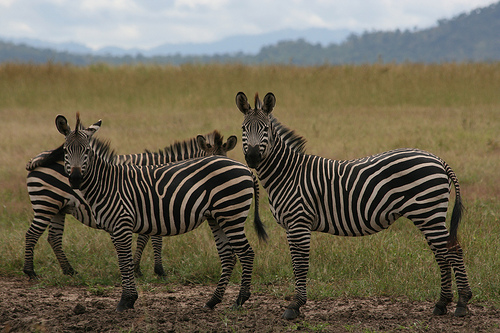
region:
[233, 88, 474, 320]
zebra is next to zebra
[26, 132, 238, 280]
zebra is next to zebra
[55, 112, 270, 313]
zebra is next to zebra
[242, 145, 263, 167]
black nose on zebra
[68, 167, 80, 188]
black nose on zebra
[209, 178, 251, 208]
black stripe on zebra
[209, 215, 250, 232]
black stripe on zebra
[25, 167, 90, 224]
black stripe on zebra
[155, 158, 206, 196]
black stripe on zebra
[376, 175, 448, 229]
black stripe on zebra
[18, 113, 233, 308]
zebra swinging her tail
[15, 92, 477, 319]
three zebras standing together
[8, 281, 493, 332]
patch of dirt zebras are standing on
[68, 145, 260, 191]
black noses of the zebra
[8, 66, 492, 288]
grass pasture behind zebras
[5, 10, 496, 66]
tree covered hillside in the distance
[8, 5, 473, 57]
cloud filled sky above hillside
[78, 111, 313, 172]
black and white manes on the zebra's necks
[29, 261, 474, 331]
hooves of the zebras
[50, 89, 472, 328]
two zebras looking in the same direction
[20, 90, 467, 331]
Three zebras standing in a field.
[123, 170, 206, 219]
Striped pattern on a zebra.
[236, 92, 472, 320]
A zebra standing in a field.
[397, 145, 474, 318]
Rear end of a zebra.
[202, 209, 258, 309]
Hind legs of a zebra.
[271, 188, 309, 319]
Front legs of a zebra.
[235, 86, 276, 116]
Ears on top of a zebra's head.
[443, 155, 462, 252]
The tail of a zebra.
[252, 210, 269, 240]
The tuft of a zebra's tail.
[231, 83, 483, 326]
zebra looking at camera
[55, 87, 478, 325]
two zebras looking toward camera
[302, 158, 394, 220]
black and white zebra pattern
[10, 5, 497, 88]
horizon grassland with mountains in distance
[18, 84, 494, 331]
zebras on dirt standing near grass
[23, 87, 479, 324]
black and white striped zebras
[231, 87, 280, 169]
face of zebra with black nose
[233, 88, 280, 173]
face of zebra with both ears forward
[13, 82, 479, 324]
Zebra in a grassy plain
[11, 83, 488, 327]
Zebra in a grassy plain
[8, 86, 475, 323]
Zebra in a grassy plain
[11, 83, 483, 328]
Zebra in a grassy plain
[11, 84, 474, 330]
Zebra in a grassy plain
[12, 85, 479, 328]
Zebra in a grassy plain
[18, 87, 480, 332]
Zebra in a grassy plain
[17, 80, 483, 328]
Zebra in a grassy plain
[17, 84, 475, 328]
Zebra in a grassy plain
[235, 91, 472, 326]
zebra is behind zebra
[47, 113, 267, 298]
zebra standing in front of zebra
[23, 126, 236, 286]
zebra is behind zebra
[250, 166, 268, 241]
tail is on the back of the zebra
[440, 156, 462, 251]
tail is apart of zebra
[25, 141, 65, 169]
tail is on the back of the zebras behind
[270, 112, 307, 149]
hair is on the back of the neck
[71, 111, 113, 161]
hair is on the top of the zebras head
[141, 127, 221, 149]
hair is on the top of the zebra head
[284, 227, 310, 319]
leg is apart of zebra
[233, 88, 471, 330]
Black and white zebra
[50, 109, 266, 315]
Black and white zebra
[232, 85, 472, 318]
Black and white zebra standing by another zebra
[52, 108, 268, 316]
Black and white zebra standing by another zebra